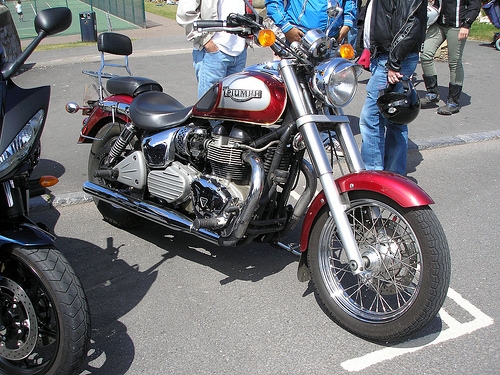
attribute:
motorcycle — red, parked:
[64, 2, 450, 341]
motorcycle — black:
[0, 7, 92, 373]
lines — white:
[291, 185, 493, 373]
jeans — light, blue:
[359, 52, 418, 178]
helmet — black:
[376, 74, 420, 127]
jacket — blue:
[265, 1, 358, 39]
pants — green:
[420, 23, 467, 86]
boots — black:
[418, 74, 463, 116]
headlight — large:
[328, 60, 364, 107]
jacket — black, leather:
[356, 1, 429, 71]